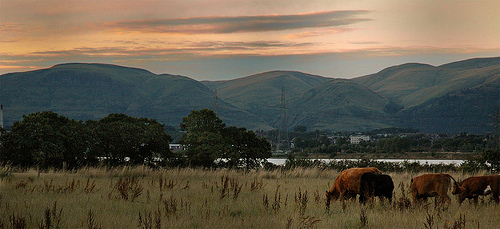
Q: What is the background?
A: Hills.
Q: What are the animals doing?
A: Grazing.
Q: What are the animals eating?
A: Grass.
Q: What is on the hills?
A: Grass.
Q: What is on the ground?
A: Brush.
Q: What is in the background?
A: Lake.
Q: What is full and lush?
A: Trees.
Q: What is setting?
A: Sun.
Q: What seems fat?
A: Cows.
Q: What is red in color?
A: Sky.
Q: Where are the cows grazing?
A: In the grass.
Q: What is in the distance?
A: Hills.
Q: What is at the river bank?
A: Trees.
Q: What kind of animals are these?
A: Cows.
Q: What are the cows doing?
A: Grazing.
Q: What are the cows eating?
A: Grass.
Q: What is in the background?
A: Mountains.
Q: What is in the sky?
A: Clouds.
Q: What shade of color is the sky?
A: Pink and grey.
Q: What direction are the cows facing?
A: Left.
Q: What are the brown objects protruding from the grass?
A: Brown plants.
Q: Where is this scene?
A: Mountains.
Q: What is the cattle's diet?
A: Vegetarian.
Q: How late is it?
A: Nearing dusk.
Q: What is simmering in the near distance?
A: A body of water.